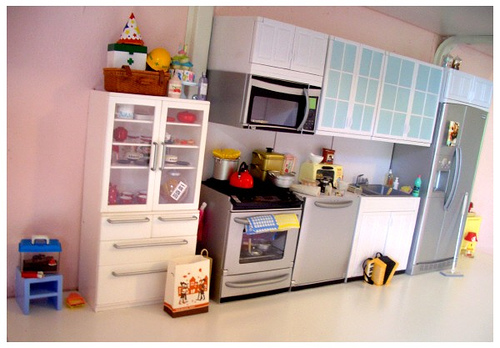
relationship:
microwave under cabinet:
[205, 65, 326, 141] [208, 13, 334, 91]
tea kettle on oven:
[223, 159, 262, 194] [201, 177, 305, 303]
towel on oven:
[242, 211, 279, 241] [201, 177, 305, 303]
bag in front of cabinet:
[156, 243, 218, 321] [77, 84, 216, 319]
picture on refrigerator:
[441, 116, 462, 149] [381, 95, 491, 281]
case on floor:
[355, 247, 402, 292] [9, 245, 497, 345]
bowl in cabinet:
[174, 109, 200, 126] [78, 89, 215, 214]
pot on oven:
[266, 166, 301, 192] [201, 177, 305, 303]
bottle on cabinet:
[194, 67, 212, 103] [78, 89, 215, 214]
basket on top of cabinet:
[99, 62, 175, 100] [78, 89, 215, 214]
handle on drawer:
[103, 215, 152, 229] [78, 204, 157, 246]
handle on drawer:
[157, 213, 200, 232] [151, 209, 205, 239]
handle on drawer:
[110, 236, 197, 253] [76, 232, 201, 271]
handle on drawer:
[108, 264, 171, 280] [74, 256, 177, 310]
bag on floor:
[156, 243, 218, 321] [9, 245, 497, 345]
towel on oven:
[242, 211, 279, 241] [218, 207, 309, 274]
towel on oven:
[271, 210, 304, 235] [218, 207, 309, 274]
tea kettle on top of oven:
[223, 159, 262, 194] [201, 177, 305, 303]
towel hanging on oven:
[242, 211, 279, 241] [201, 177, 305, 303]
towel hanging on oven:
[271, 210, 304, 235] [201, 177, 305, 303]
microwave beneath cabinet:
[205, 65, 326, 141] [208, 13, 334, 91]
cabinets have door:
[203, 12, 495, 154] [314, 35, 389, 143]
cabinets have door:
[203, 12, 495, 154] [371, 47, 450, 154]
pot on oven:
[206, 151, 243, 183] [201, 177, 305, 303]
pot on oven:
[250, 143, 290, 185] [201, 177, 305, 303]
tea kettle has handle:
[223, 159, 262, 194] [234, 159, 251, 171]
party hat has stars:
[113, 8, 148, 48] [126, 29, 139, 42]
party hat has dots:
[113, 8, 148, 48] [129, 23, 136, 31]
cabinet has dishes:
[77, 84, 216, 319] [166, 150, 193, 169]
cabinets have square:
[203, 12, 495, 154] [325, 35, 348, 75]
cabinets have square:
[203, 12, 495, 154] [321, 67, 345, 100]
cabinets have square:
[203, 12, 495, 154] [320, 98, 342, 131]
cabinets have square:
[203, 12, 495, 154] [380, 51, 407, 86]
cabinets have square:
[203, 12, 495, 154] [413, 60, 435, 97]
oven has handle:
[218, 207, 309, 274] [231, 212, 302, 230]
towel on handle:
[242, 211, 279, 241] [231, 212, 302, 230]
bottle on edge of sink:
[411, 167, 425, 201] [350, 168, 426, 205]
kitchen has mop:
[6, 5, 498, 346] [436, 190, 475, 282]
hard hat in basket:
[147, 43, 176, 76] [99, 62, 175, 100]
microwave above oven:
[205, 65, 326, 141] [201, 177, 305, 303]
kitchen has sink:
[6, 5, 498, 346] [350, 168, 426, 205]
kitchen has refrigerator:
[6, 5, 498, 346] [381, 95, 491, 281]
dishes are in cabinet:
[166, 150, 193, 169] [78, 89, 215, 214]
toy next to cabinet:
[167, 41, 197, 72] [208, 13, 334, 91]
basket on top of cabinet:
[99, 62, 175, 100] [77, 84, 216, 319]